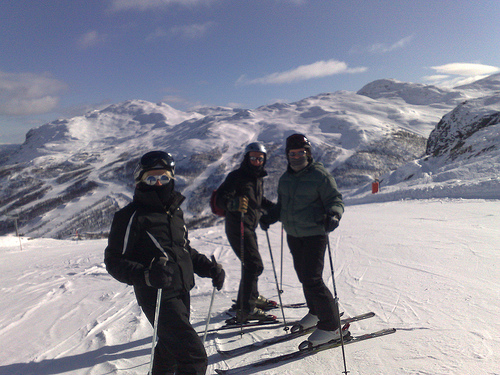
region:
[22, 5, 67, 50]
white clouds in blue sky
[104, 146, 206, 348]
skier dressed in black ooutfit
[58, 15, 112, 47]
white clouds in blue sky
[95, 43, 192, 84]
white clouds in blue sky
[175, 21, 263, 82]
white clouds in blue sky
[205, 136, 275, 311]
skier dressed in black outfit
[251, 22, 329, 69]
white clouds in blue sky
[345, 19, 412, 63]
white clouds in blue sky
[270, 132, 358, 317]
skier dressed in black outfit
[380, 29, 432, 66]
white clouds in blue sky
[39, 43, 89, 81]
white clouds in blue sky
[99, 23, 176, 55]
white clouds in blue sky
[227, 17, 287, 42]
white clouds in blue sky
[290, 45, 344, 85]
white clouds in blue sky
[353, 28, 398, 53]
white clouds in blue sky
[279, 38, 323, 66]
white clouds in blue sky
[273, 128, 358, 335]
skier in snow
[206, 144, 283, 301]
skier in snow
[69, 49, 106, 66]
white clouds in blue sky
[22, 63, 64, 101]
white clouds in blue sky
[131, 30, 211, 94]
white clouds in blue sky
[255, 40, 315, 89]
white clouds in blue sky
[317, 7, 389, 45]
white clouds in blue sky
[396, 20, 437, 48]
white clouds in blue sky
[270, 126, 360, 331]
person skiing down hill side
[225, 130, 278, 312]
person skiing down hill side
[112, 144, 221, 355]
person skiing down hill side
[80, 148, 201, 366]
skier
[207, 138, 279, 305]
male skier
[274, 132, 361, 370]
male skier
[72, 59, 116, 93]
white clouds in blue sky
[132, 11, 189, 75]
white clouds in blue sky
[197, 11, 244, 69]
white clouds in blue sky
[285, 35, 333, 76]
white clouds in blue sky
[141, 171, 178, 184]
goggles on a skier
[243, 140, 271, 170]
a gray helmet on a skier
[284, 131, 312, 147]
a black helmet on a skier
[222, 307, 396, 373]
a pair of gray skis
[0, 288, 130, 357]
ski tracks in the snow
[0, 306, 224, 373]
the shadow of a skier on the snow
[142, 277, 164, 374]
a silver colored ski pole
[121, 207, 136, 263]
a reflective stripe on a coat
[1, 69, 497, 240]
a mountain in the background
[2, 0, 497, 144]
a blue sky with a few clouds